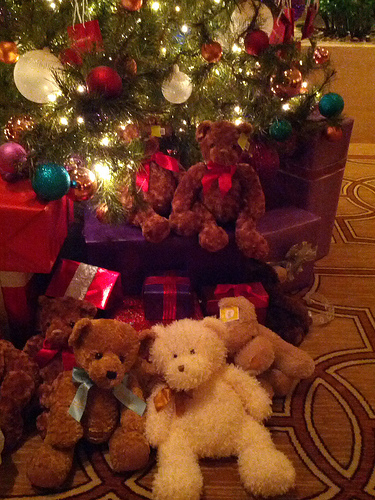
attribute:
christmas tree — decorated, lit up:
[0, 2, 327, 230]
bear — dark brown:
[25, 312, 157, 492]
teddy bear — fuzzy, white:
[145, 313, 305, 492]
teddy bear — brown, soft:
[22, 315, 149, 490]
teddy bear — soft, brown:
[12, 283, 89, 396]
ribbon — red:
[30, 339, 57, 356]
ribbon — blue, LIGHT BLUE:
[65, 366, 148, 425]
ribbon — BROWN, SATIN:
[151, 386, 193, 418]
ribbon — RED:
[143, 272, 184, 317]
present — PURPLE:
[141, 269, 200, 322]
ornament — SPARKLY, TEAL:
[30, 159, 71, 199]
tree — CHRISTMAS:
[10, 8, 343, 223]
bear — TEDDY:
[171, 118, 270, 261]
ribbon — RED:
[198, 162, 237, 193]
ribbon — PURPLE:
[279, 158, 344, 185]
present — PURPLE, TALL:
[280, 111, 352, 261]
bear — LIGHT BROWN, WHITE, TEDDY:
[140, 315, 300, 492]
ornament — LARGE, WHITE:
[10, 46, 67, 109]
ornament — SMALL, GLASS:
[160, 60, 194, 103]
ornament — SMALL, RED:
[198, 38, 224, 65]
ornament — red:
[88, 59, 126, 102]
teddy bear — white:
[137, 310, 292, 498]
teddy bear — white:
[126, 318, 295, 498]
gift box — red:
[201, 272, 268, 320]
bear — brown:
[158, 130, 280, 242]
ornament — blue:
[39, 161, 92, 199]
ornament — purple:
[0, 133, 42, 175]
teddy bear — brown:
[171, 118, 275, 260]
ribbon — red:
[198, 159, 242, 194]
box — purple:
[140, 269, 199, 322]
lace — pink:
[159, 270, 179, 317]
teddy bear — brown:
[21, 289, 97, 382]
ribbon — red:
[36, 337, 80, 368]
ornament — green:
[29, 161, 76, 199]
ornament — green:
[318, 90, 346, 121]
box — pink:
[207, 267, 273, 317]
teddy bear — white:
[161, 325, 282, 453]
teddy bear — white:
[138, 318, 271, 498]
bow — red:
[194, 160, 249, 198]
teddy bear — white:
[133, 329, 292, 485]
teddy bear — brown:
[50, 309, 144, 459]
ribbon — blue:
[54, 356, 137, 401]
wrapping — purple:
[130, 274, 172, 310]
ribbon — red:
[159, 265, 182, 301]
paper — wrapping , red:
[93, 284, 118, 296]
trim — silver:
[70, 262, 104, 293]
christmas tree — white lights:
[82, 156, 130, 187]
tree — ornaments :
[117, 26, 286, 130]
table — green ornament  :
[26, 160, 85, 197]